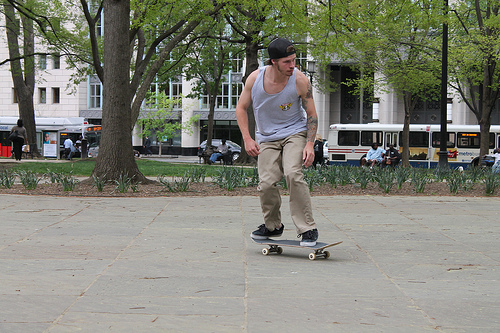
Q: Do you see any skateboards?
A: Yes, there is a skateboard.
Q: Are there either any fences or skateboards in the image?
A: Yes, there is a skateboard.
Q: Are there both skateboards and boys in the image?
A: No, there is a skateboard but no boys.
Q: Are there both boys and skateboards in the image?
A: No, there is a skateboard but no boys.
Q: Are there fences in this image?
A: No, there are no fences.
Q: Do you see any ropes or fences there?
A: No, there are no fences or ropes.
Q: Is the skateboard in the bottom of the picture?
A: Yes, the skateboard is in the bottom of the image.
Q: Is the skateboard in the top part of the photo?
A: No, the skateboard is in the bottom of the image.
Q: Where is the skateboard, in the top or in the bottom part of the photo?
A: The skateboard is in the bottom of the image.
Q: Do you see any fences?
A: No, there are no fences.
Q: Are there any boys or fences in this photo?
A: No, there are no fences or boys.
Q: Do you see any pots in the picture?
A: No, there are no pots.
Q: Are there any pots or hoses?
A: No, there are no pots or hoses.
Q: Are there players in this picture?
A: No, there are no players.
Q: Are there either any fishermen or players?
A: No, there are no players or fishermen.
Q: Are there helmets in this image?
A: No, there are no helmets.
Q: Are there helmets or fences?
A: No, there are no helmets or fences.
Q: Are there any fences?
A: No, there are no fences.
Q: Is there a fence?
A: No, there are no fences.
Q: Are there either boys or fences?
A: No, there are no fences or boys.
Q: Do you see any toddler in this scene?
A: No, there are no toddlers.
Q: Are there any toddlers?
A: No, there are no toddlers.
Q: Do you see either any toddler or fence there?
A: No, there are no toddlers or fences.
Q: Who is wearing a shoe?
A: The man is wearing a shoe.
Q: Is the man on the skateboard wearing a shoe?
A: Yes, the man is wearing a shoe.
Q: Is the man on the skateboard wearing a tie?
A: No, the man is wearing a shoe.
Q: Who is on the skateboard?
A: The man is on the skateboard.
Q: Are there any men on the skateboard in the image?
A: Yes, there is a man on the skateboard.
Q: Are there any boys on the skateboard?
A: No, there is a man on the skateboard.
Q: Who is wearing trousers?
A: The man is wearing trousers.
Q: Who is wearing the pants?
A: The man is wearing trousers.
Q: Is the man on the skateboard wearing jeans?
A: No, the man is wearing trousers.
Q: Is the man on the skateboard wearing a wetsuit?
A: No, the man is wearing a shoe.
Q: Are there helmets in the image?
A: No, there are no helmets.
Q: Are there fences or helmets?
A: No, there are no helmets or fences.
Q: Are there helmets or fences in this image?
A: No, there are no helmets or fences.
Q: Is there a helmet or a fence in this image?
A: No, there are no helmets or fences.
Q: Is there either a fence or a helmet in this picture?
A: No, there are no helmets or fences.